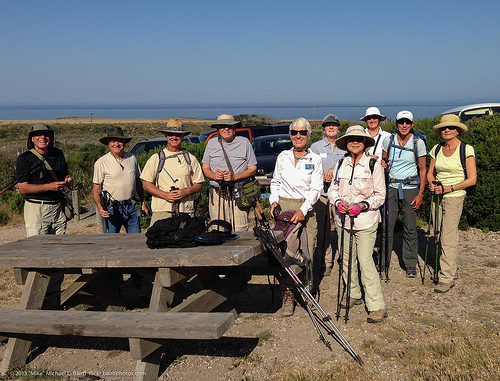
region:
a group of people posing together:
[8, 103, 478, 338]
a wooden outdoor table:
[0, 218, 284, 368]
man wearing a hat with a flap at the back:
[18, 119, 61, 154]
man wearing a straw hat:
[153, 114, 194, 139]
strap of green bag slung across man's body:
[204, 114, 266, 214]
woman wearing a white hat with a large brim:
[327, 118, 384, 159]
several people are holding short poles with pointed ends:
[93, 120, 450, 332]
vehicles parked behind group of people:
[119, 99, 495, 208]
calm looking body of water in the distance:
[2, 99, 452, 123]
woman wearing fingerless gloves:
[326, 194, 369, 229]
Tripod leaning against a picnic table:
[250, 213, 365, 368]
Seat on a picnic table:
[0, 303, 248, 353]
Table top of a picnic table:
[0, 220, 282, 280]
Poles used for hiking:
[332, 205, 352, 326]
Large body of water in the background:
[5, 104, 497, 117]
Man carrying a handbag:
[202, 109, 265, 223]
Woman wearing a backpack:
[424, 113, 484, 285]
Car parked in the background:
[245, 130, 305, 178]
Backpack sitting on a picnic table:
[137, 210, 242, 253]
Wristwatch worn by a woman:
[447, 183, 457, 193]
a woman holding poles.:
[326, 116, 396, 332]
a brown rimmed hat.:
[156, 96, 195, 142]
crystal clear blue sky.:
[3, 0, 498, 103]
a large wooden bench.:
[0, 224, 290, 376]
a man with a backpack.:
[134, 116, 209, 236]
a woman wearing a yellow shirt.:
[424, 109, 479, 291]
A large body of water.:
[4, 99, 499, 114]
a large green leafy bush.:
[380, 107, 495, 235]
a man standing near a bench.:
[10, 111, 81, 239]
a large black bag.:
[124, 194, 240, 251]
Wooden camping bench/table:
[2, 225, 283, 372]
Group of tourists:
[16, 110, 482, 231]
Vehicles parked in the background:
[125, 111, 290, 158]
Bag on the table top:
[146, 206, 236, 246]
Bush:
[470, 111, 495, 226]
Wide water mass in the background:
[5, 95, 360, 115]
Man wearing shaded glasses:
[288, 125, 310, 139]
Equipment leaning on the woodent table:
[245, 210, 320, 360]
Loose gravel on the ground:
[245, 315, 456, 373]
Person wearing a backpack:
[390, 106, 423, 271]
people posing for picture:
[34, 96, 476, 311]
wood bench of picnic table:
[82, 297, 240, 351]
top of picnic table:
[36, 223, 126, 275]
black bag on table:
[141, 203, 238, 260]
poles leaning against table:
[251, 223, 360, 368]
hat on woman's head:
[431, 109, 474, 142]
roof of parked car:
[457, 95, 495, 122]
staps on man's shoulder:
[152, 146, 200, 176]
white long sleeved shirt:
[262, 148, 327, 218]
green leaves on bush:
[475, 134, 498, 189]